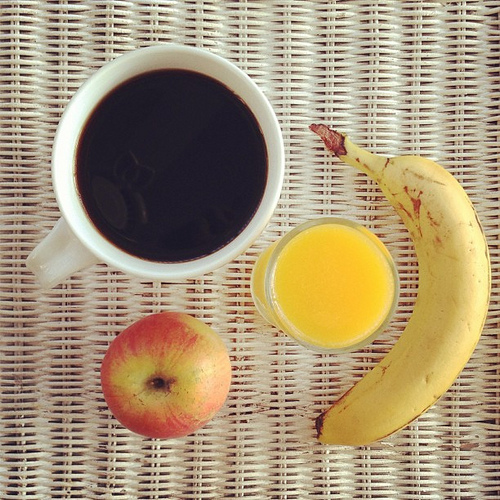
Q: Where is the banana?
A: Next to the glass.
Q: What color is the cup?
A: White.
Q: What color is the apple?
A: Red and yellow.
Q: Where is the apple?
A: In front of the cup.